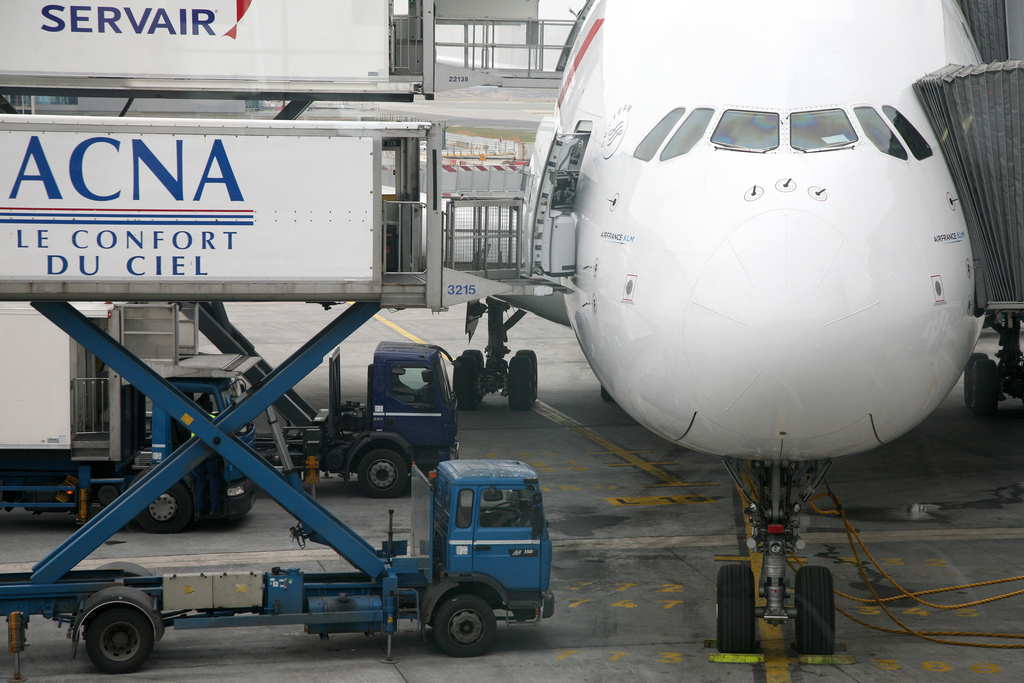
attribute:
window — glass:
[630, 100, 689, 155]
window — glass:
[709, 106, 783, 154]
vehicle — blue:
[402, 448, 571, 643]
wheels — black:
[710, 551, 845, 664]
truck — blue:
[6, 439, 560, 675]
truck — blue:
[137, 336, 477, 520]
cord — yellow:
[809, 467, 993, 623]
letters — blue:
[8, 132, 250, 217]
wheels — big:
[442, 305, 546, 416]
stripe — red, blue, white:
[548, 7, 616, 122]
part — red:
[217, 1, 267, 51]